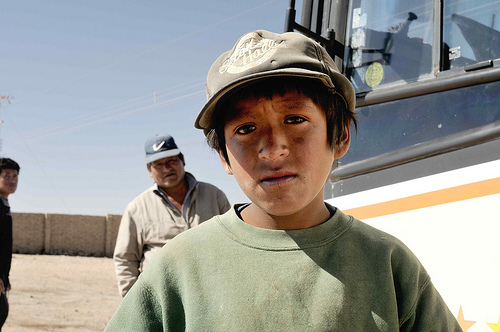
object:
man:
[108, 129, 237, 296]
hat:
[139, 131, 184, 167]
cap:
[190, 27, 361, 134]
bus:
[284, 0, 500, 194]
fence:
[9, 208, 121, 260]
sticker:
[363, 59, 386, 88]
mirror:
[285, 2, 353, 57]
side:
[282, 1, 386, 63]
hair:
[199, 77, 362, 160]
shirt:
[111, 175, 233, 283]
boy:
[103, 27, 463, 331]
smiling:
[215, 93, 340, 231]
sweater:
[101, 204, 461, 331]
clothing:
[0, 194, 17, 330]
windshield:
[346, 1, 407, 85]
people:
[0, 130, 190, 324]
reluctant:
[4, 139, 186, 200]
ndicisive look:
[221, 85, 321, 215]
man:
[1, 154, 24, 327]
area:
[18, 243, 101, 328]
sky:
[3, 5, 197, 126]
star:
[456, 300, 478, 331]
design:
[216, 30, 285, 79]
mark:
[292, 135, 306, 144]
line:
[355, 175, 499, 214]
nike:
[152, 141, 166, 155]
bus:
[352, 4, 494, 241]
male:
[3, 130, 221, 289]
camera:
[1, 4, 495, 331]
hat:
[202, 19, 345, 108]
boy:
[119, 13, 453, 329]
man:
[104, 130, 271, 330]